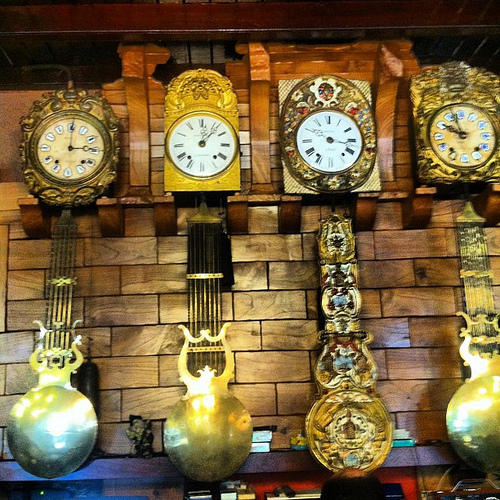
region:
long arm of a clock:
[207, 130, 217, 140]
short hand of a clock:
[338, 138, 343, 142]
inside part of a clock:
[61, 125, 75, 161]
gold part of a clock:
[178, 179, 203, 191]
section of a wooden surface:
[399, 254, 419, 327]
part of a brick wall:
[270, 297, 293, 344]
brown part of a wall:
[203, 408, 232, 430]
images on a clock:
[336, 413, 379, 438]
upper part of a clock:
[189, 75, 216, 107]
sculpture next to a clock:
[133, 430, 143, 441]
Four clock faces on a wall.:
[28, 103, 498, 180]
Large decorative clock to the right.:
[279, 69, 395, 469]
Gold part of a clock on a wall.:
[161, 70, 243, 197]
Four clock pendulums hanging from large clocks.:
[6, 201, 499, 475]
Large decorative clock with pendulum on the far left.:
[8, 82, 123, 479]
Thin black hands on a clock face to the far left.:
[67, 113, 98, 153]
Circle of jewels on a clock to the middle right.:
[317, 79, 334, 103]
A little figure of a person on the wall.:
[123, 413, 155, 460]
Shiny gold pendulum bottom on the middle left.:
[164, 318, 254, 480]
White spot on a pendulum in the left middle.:
[178, 368, 217, 415]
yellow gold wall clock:
[161, 66, 246, 197]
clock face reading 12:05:
[162, 112, 234, 177]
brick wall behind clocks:
[245, 242, 306, 400]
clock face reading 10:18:
[295, 102, 368, 179]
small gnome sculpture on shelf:
[125, 410, 157, 464]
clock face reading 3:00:
[17, 78, 127, 212]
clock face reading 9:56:
[427, 97, 497, 171]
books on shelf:
[389, 423, 420, 451]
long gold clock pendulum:
[157, 200, 254, 482]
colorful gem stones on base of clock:
[308, 72, 345, 107]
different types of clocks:
[41, 75, 486, 498]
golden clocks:
[28, 52, 495, 403]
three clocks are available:
[10, 80, 427, 488]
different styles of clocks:
[24, 47, 488, 244]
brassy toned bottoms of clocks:
[50, 224, 357, 494]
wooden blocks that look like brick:
[27, 154, 473, 434]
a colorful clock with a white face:
[277, 35, 415, 238]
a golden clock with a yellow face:
[49, 72, 131, 229]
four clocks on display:
[25, 59, 469, 482]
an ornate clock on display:
[251, 47, 444, 486]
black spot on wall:
[409, 253, 438, 295]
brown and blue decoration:
[320, 285, 370, 317]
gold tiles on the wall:
[231, 285, 291, 352]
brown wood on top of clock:
[44, 2, 251, 62]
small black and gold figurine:
[121, 402, 159, 473]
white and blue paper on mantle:
[378, 412, 430, 460]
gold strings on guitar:
[170, 249, 230, 371]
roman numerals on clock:
[165, 118, 251, 189]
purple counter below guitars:
[388, 433, 450, 482]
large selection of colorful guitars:
[15, 109, 463, 482]